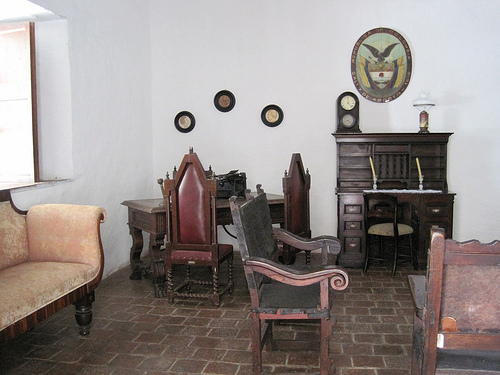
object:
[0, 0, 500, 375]
room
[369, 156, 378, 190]
candle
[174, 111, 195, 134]
frame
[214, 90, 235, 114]
circle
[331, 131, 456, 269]
desk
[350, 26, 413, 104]
frame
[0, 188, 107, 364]
couch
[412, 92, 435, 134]
lamp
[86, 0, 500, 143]
wall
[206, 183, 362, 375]
sette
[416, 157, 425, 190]
ink containers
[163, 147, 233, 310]
chair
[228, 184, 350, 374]
chair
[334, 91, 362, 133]
clock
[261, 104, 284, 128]
black record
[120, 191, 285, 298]
desk area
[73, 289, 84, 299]
wood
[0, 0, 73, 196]
window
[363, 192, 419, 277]
chair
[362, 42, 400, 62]
eagle